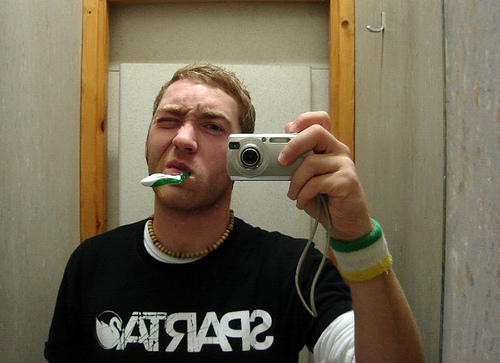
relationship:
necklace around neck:
[143, 198, 248, 271] [104, 182, 263, 312]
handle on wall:
[364, 11, 386, 33] [266, 21, 461, 163]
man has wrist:
[43, 60, 428, 363] [329, 212, 390, 293]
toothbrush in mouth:
[147, 155, 207, 192] [165, 158, 208, 168]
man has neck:
[259, 180, 383, 290] [104, 182, 263, 312]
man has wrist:
[259, 180, 383, 290] [329, 212, 390, 293]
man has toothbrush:
[259, 180, 383, 290] [147, 155, 207, 192]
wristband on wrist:
[325, 207, 392, 263] [329, 212, 390, 293]